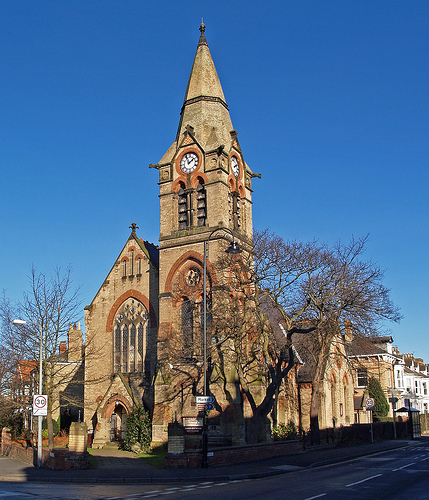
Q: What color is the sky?
A: Blue.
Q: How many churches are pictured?
A: One.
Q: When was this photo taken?
A: Day time.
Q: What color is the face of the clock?
A: White.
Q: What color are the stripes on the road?
A: White.